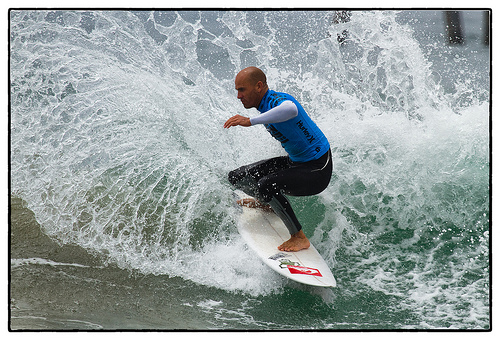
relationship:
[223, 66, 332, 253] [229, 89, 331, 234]
man wearing wetsuit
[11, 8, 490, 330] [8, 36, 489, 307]
ocean has wave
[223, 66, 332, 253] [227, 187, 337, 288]
man riding surfboard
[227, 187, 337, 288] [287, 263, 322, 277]
surfboard has logo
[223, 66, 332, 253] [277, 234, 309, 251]
man has foot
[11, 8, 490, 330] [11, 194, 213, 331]
ocean has water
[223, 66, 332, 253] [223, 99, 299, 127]
man has arm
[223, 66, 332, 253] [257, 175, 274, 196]
man has knee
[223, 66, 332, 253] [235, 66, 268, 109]
man has head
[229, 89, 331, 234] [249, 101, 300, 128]
wetsuit has sleeve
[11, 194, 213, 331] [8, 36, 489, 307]
water in front of wave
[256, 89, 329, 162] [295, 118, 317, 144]
shirt has logo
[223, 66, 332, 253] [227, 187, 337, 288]
man on surfboard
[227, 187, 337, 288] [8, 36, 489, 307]
surfboard on wave